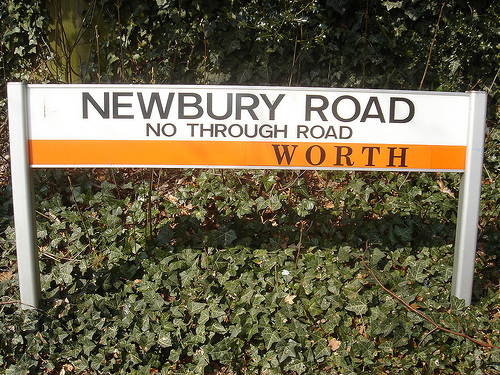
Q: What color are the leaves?
A: Green.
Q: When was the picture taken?
A: Daytime.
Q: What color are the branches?
A: Brown.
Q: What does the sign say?
A: Newbury Road No Through Road Worth.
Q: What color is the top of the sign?
A: White.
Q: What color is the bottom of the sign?
A: Orange.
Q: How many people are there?
A: 0.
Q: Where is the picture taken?
A: Newbury road.